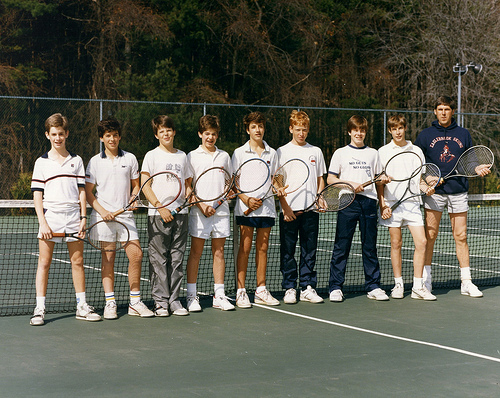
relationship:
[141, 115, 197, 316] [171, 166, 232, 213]
boy holding tennis racket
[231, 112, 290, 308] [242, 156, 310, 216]
boy holding tennis racket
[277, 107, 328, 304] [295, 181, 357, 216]
boy holding racket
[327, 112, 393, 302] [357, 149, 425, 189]
boy holding tennis racket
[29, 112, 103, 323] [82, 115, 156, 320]
boy standing next to boy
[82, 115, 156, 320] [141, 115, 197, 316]
boy standing next to boy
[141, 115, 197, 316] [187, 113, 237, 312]
boy standing next to boy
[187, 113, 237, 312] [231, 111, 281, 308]
boy standing next to boy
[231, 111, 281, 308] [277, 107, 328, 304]
boy standing next to boy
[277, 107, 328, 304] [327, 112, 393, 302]
boy standing next to boy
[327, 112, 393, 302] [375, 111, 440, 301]
boy standing next to boy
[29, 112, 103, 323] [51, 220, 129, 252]
boy holding racket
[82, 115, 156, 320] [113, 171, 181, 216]
boy holding racket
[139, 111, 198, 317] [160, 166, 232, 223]
boy holding racket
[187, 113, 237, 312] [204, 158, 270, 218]
boy holding racket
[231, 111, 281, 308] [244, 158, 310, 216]
boy holding racket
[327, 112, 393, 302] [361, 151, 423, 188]
boy holding racket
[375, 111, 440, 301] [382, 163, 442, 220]
boy holding racket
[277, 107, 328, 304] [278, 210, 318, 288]
boy wearing jeans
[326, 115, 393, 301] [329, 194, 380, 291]
boy wearing jeans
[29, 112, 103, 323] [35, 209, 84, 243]
boy wearing shorts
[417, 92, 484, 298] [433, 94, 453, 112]
man has hair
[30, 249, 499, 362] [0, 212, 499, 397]
line on court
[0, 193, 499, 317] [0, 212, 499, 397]
net on court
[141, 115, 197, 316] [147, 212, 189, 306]
boy wearing pants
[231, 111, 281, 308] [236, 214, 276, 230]
boy wearing shorts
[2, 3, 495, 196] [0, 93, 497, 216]
trees behind fence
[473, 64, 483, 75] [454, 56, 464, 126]
light on top of pole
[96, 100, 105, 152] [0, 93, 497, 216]
pole on fence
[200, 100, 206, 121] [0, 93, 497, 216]
pole on fence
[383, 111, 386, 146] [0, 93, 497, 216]
pole on fence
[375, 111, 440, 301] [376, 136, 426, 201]
boy wearing shirt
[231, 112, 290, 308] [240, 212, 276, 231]
boy wearing shorts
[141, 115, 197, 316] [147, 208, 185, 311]
boy wearing pants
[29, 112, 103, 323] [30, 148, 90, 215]
boy wearing shirt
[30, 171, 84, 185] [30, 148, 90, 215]
stripe on shirt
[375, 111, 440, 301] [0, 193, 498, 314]
boy standing in front of net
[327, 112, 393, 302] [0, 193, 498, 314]
boy standing in front of net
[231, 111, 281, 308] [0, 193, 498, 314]
boy standing in front of net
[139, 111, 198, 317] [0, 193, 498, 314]
boy standing in front of net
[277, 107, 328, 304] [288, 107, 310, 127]
boy has hair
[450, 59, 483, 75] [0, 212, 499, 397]
light on court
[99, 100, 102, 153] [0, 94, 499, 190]
pole on fence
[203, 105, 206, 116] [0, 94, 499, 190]
pole on fence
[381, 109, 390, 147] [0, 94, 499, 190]
pole on fence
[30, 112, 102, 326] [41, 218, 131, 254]
boy holding racket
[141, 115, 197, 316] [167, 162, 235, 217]
boy holding racket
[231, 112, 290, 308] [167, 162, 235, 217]
boy holding racket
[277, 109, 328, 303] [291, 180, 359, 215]
boy holding racket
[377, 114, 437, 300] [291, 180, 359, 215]
boy holding racket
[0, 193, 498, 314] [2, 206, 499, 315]
net has strings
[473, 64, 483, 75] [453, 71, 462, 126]
light on pole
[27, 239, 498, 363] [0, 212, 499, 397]
lines on court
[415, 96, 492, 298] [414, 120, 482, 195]
man wearing sweatshirt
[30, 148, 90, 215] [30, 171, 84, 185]
shirt has stripe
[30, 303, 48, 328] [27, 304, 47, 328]
sneaker on foot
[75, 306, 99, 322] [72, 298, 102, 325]
sneaker on foot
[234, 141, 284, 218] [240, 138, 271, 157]
shirt has collar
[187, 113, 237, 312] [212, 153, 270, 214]
boy holding racket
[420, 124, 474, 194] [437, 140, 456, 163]
sweatshirt with emblem